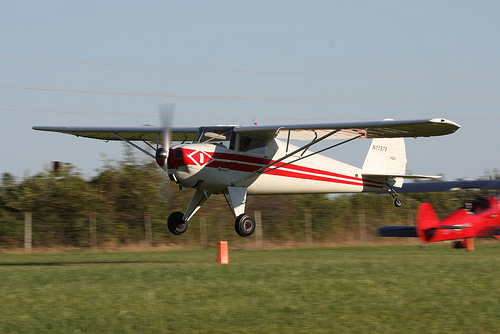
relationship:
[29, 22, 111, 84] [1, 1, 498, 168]
clouds in sky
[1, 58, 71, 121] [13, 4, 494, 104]
clouds in sky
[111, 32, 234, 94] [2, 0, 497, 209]
clouds in sky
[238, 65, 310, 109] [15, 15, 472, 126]
clouds in sky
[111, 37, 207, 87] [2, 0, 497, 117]
clouds in sky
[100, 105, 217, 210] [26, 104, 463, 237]
propeller on plane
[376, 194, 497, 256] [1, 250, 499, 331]
plane on ground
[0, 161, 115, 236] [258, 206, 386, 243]
tree behind fence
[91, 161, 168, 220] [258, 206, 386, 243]
tree behind fence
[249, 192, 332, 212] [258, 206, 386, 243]
tree behind fence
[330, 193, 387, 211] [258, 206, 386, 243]
tree behind fence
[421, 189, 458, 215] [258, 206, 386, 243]
tree behind fence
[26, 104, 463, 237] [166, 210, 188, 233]
plane has wheel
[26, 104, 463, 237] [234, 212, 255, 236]
plane has wheel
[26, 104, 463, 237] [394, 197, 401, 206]
plane has wheel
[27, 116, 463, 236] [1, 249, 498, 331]
white plane slightly above ground level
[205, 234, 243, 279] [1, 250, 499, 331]
cone on ground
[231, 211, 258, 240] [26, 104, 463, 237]
tire on plane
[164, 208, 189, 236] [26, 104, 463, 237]
tire on plane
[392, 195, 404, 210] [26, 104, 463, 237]
tire on plane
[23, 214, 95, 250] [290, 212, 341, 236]
posts hold up fence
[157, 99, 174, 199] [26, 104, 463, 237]
propeller on plane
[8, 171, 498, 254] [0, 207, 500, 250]
trees on side of fence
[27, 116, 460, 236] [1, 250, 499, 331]
airplane above ground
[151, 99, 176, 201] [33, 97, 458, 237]
propeller on airplane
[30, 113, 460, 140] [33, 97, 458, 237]
wing on airplane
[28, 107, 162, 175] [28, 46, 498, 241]
wing on airplane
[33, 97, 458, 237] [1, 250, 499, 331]
airplane on ground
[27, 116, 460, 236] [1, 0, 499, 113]
airplane ascending into air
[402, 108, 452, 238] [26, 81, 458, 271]
tail fine view of a red plane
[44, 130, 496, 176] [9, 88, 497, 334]
group of planes at an airport